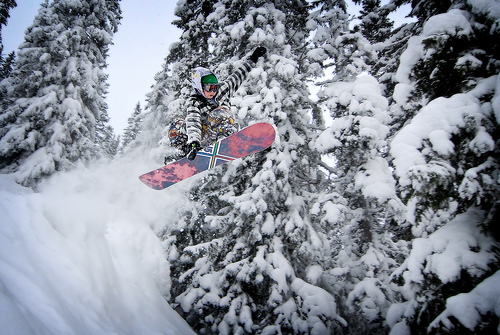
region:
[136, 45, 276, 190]
a person is snowboarding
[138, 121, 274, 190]
snowboard is red and black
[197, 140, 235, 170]
colorful X design underneath snowboard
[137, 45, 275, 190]
snowboarder is doing a jump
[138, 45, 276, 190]
person holding the snowboard with their right hand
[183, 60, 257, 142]
black and white plaid coat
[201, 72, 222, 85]
green baseball cap is underneath a hood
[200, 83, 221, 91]
ski goggles covering a person's eyes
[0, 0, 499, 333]
snow covered evergreen trees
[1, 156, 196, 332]
snow is covering the ground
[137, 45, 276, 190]
person on top of a snowboard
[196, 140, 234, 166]
X printed on the snowboard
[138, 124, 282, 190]
the snowboard is red and black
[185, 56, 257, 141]
person wearing a striped jacket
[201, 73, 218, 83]
a green helmet above ski goggles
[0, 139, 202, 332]
a plume of white snow behind the snowboard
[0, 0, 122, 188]
tall snowy pine tree in front of the sky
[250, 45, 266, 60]
person is wearing black mittens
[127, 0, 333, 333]
tree behind person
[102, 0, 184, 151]
sky behind tree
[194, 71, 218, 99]
ead of a person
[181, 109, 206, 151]
leg of a person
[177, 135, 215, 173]
feet of a person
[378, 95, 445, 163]
snow on a tree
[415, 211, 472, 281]
snow on a tree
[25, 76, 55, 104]
snow on a tree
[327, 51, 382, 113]
snow on a tree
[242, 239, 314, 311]
snow on a tree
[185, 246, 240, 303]
snow on a tree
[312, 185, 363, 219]
snow on a tree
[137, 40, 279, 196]
a snowboarder flying through the air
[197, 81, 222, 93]
goggles on the person's face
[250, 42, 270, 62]
a black glove on the person's hand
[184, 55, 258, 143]
a thick black and white plaid coat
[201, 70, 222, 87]
a green hat on the snowboarder's head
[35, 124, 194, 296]
a bunch of snow being kicked up into the air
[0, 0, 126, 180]
a large pine tree covered in snow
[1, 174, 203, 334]
a steep hill covered in snow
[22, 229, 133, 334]
snowboard tracks in the snow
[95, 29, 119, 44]
snow on a tree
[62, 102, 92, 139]
snow on a tree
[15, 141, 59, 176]
snow on a tree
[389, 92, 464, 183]
snow on a tree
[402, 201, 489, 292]
snow on a tree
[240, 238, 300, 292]
snow on a tree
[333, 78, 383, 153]
snow on a tree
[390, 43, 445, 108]
snow on a tree